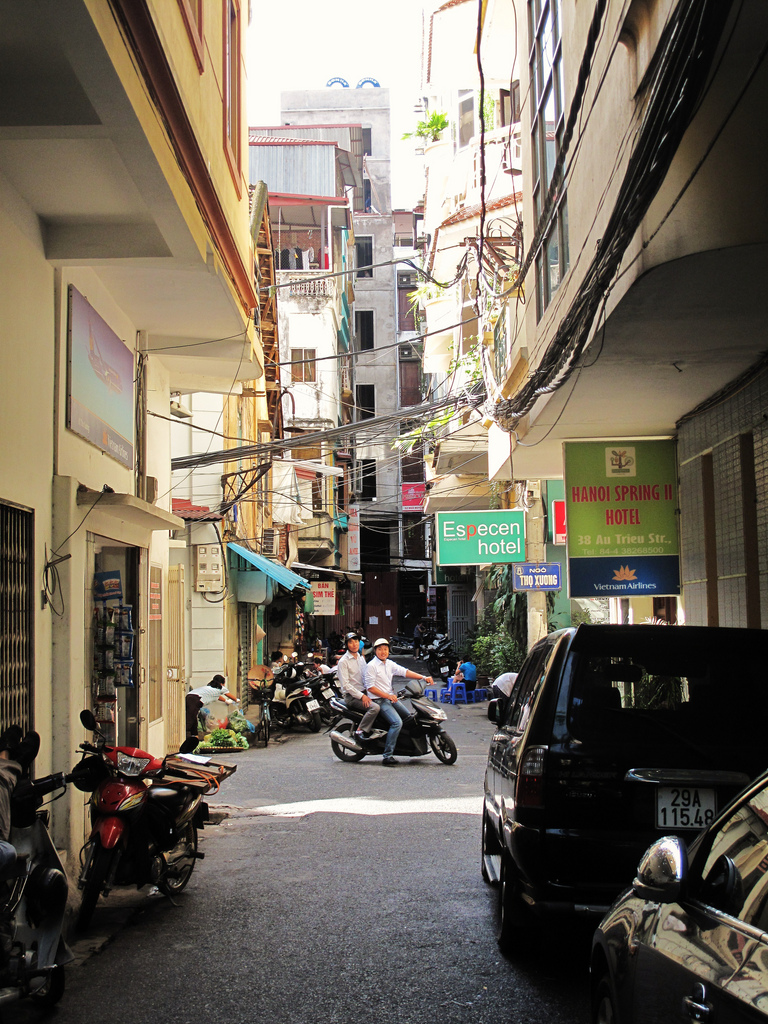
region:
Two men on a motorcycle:
[314, 623, 464, 772]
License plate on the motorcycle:
[297, 692, 322, 716]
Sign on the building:
[425, 506, 528, 570]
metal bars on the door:
[4, 497, 36, 788]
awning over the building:
[222, 533, 314, 605]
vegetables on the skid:
[197, 722, 256, 758]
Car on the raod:
[468, 618, 763, 967]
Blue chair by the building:
[444, 669, 472, 703]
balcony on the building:
[265, 199, 343, 306]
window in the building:
[287, 344, 322, 386]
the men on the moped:
[328, 633, 459, 769]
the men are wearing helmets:
[335, 631, 431, 765]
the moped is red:
[74, 710, 235, 914]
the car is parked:
[478, 621, 766, 961]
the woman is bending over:
[185, 674, 240, 745]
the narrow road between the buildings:
[1, 1, 766, 1022]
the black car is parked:
[588, 764, 764, 1022]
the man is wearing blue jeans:
[363, 636, 433, 770]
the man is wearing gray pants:
[336, 631, 377, 740]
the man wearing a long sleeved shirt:
[365, 638, 433, 766]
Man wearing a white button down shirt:
[362, 634, 432, 763]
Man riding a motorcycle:
[334, 631, 375, 737]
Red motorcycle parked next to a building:
[57, 704, 235, 934]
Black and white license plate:
[659, 782, 718, 832]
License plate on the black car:
[656, 780, 720, 832]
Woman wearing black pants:
[181, 672, 243, 747]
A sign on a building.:
[55, 303, 139, 463]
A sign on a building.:
[430, 506, 527, 564]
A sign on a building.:
[550, 502, 575, 533]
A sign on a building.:
[507, 559, 568, 593]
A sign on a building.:
[402, 482, 432, 510]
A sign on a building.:
[341, 503, 366, 574]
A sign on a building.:
[304, 563, 344, 617]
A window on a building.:
[295, 344, 322, 384]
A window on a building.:
[286, 413, 326, 465]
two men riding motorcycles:
[329, 628, 433, 770]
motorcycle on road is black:
[315, 685, 462, 770]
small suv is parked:
[471, 602, 766, 960]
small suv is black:
[475, 617, 766, 954]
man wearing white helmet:
[371, 634, 390, 649]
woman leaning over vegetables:
[183, 668, 241, 754]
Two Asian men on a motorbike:
[328, 631, 457, 764]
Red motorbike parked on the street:
[67, 710, 235, 929]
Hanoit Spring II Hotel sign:
[562, 438, 680, 602]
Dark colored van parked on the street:
[480, 623, 767, 958]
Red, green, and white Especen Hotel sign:
[433, 511, 528, 565]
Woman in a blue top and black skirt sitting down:
[448, 653, 476, 689]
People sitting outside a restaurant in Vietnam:
[268, 650, 327, 673]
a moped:
[70, 701, 227, 900]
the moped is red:
[80, 717, 216, 902]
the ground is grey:
[326, 883, 422, 979]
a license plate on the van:
[657, 785, 710, 832]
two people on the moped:
[326, 626, 422, 720]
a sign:
[440, 509, 524, 562]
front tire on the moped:
[421, 737, 471, 758]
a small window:
[285, 339, 320, 385]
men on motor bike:
[328, 627, 456, 768]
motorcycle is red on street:
[58, 734, 231, 926]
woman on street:
[174, 669, 243, 761]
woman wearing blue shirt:
[453, 651, 483, 699]